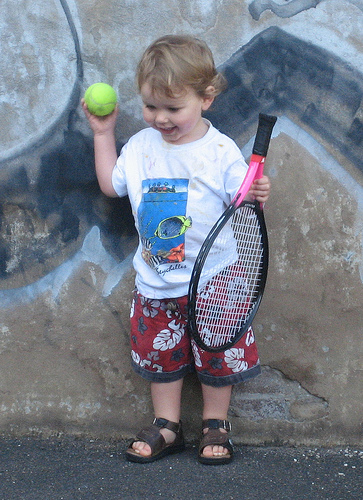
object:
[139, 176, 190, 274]
picture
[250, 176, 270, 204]
hand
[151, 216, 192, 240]
fish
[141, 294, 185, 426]
leg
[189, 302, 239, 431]
leg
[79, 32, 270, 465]
boy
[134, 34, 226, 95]
blonde hair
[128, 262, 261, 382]
print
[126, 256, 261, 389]
shorts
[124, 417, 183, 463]
sandal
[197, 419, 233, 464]
sandal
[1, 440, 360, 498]
ground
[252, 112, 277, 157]
handle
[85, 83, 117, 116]
ball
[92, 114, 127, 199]
arm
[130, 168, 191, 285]
print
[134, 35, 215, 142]
head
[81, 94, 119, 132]
hand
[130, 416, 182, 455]
feet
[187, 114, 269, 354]
racket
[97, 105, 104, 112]
stain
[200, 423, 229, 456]
foot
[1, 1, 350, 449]
wall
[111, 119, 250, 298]
shirt